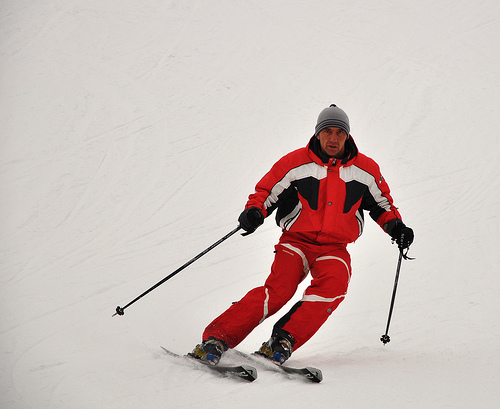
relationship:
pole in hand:
[111, 225, 241, 316] [236, 207, 263, 232]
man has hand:
[192, 102, 414, 363] [236, 207, 263, 232]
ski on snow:
[162, 339, 266, 391] [1, 0, 499, 406]